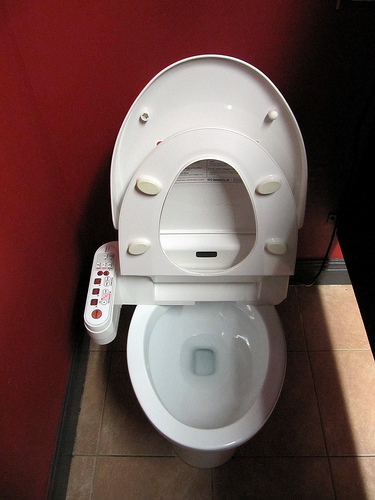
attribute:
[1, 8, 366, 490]
stall —  bathroom's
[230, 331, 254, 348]
reflection —  of light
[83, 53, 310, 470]
toilet —  restroom's,  with  drain,  with  seat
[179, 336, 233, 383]
water — toilet's, bowl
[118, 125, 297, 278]
toilet seat — toilet's,  raised up, white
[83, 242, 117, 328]
control panel — for control,  toilet's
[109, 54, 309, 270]
toilet lid —  toilet's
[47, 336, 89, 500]
border — black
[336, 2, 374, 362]
board — black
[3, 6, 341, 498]
wall — red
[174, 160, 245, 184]
sticker —  for direction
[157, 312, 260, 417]
bowl —  toilet's, white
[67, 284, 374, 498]
tiles — tan, bathroom